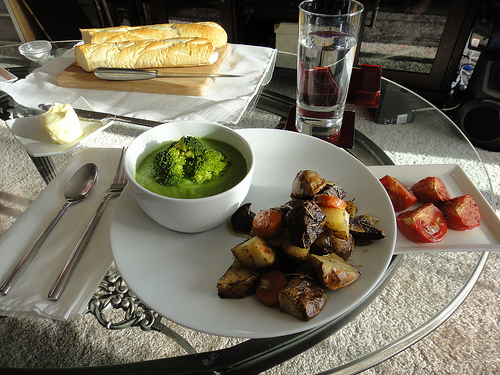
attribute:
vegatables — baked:
[215, 168, 387, 328]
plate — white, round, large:
[104, 121, 402, 344]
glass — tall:
[291, 0, 360, 148]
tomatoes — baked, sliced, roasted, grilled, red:
[378, 173, 477, 248]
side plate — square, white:
[361, 154, 499, 261]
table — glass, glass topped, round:
[0, 37, 499, 374]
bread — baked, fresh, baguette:
[71, 18, 235, 72]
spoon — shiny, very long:
[3, 161, 102, 302]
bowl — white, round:
[119, 115, 263, 244]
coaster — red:
[280, 101, 363, 152]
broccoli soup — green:
[133, 133, 248, 201]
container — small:
[16, 37, 62, 66]